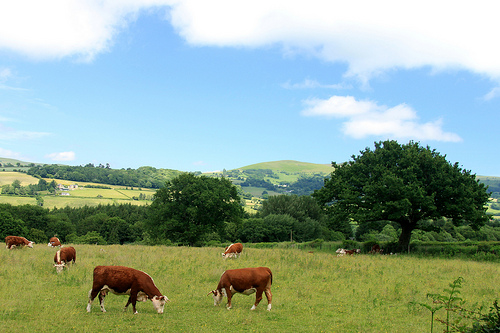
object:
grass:
[0, 240, 499, 333]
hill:
[204, 160, 341, 178]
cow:
[48, 235, 62, 249]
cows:
[219, 243, 244, 261]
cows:
[50, 246, 77, 278]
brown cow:
[4, 235, 35, 250]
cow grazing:
[5, 221, 36, 251]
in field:
[0, 136, 498, 332]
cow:
[205, 266, 273, 312]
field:
[0, 240, 499, 331]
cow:
[84, 265, 170, 316]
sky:
[0, 0, 499, 178]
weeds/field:
[407, 300, 457, 332]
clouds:
[295, 92, 463, 147]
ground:
[0, 239, 499, 333]